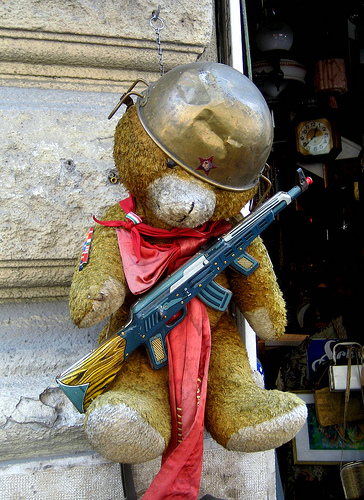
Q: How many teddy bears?
A: One.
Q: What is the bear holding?
A: A gun.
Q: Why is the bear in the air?
A: Hanging.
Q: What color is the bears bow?
A: Red.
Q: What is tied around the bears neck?
A: A bowtie.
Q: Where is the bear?
A: On the wall.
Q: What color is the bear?
A: Brown.